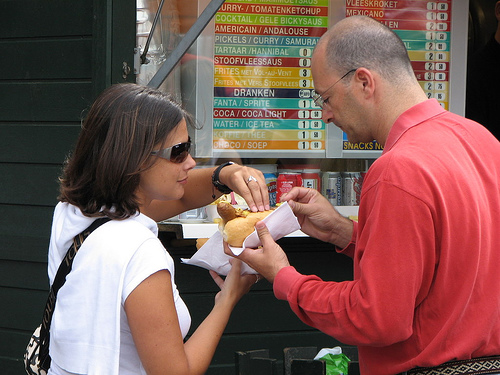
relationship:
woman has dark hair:
[63, 75, 213, 372] [63, 80, 175, 217]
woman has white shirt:
[63, 75, 213, 372] [49, 204, 196, 372]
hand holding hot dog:
[226, 231, 292, 278] [214, 199, 307, 242]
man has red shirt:
[293, 13, 498, 373] [288, 116, 495, 371]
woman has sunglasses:
[63, 75, 213, 372] [145, 137, 201, 165]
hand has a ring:
[228, 168, 278, 210] [244, 174, 259, 186]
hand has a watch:
[228, 168, 278, 210] [211, 156, 238, 193]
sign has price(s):
[197, 7, 456, 155] [296, 44, 320, 149]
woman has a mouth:
[63, 75, 213, 372] [177, 172, 189, 185]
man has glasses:
[293, 13, 498, 373] [304, 72, 367, 108]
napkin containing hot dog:
[231, 209, 300, 253] [214, 199, 307, 242]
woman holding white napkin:
[63, 75, 213, 372] [183, 233, 259, 280]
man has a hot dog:
[293, 13, 498, 373] [214, 199, 307, 242]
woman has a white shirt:
[63, 75, 213, 372] [49, 204, 196, 372]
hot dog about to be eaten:
[214, 199, 307, 242] [162, 97, 418, 284]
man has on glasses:
[293, 13, 498, 373] [304, 72, 367, 108]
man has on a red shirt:
[293, 13, 498, 373] [288, 116, 495, 371]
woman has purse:
[63, 75, 213, 372] [17, 296, 61, 370]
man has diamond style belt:
[293, 13, 498, 373] [389, 353, 491, 372]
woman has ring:
[63, 75, 213, 372] [244, 174, 259, 186]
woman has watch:
[63, 75, 213, 372] [211, 156, 238, 193]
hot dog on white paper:
[214, 199, 307, 242] [231, 209, 300, 253]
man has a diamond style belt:
[293, 13, 498, 373] [389, 353, 492, 375]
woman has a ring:
[63, 75, 213, 372] [244, 174, 259, 186]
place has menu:
[16, 8, 482, 365] [197, 7, 456, 155]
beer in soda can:
[292, 169, 365, 202] [344, 169, 363, 209]